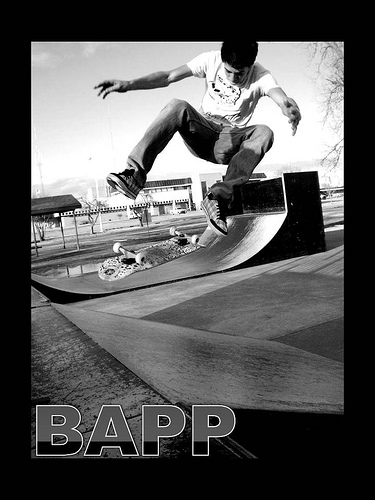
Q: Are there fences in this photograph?
A: No, there are no fences.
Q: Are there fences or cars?
A: No, there are no fences or cars.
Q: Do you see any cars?
A: No, there are no cars.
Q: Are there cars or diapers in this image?
A: No, there are no cars or diapers.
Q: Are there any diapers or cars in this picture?
A: No, there are no cars or diapers.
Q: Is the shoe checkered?
A: Yes, the shoe is checkered.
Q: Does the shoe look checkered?
A: Yes, the shoe is checkered.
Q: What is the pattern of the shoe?
A: The shoe is checkered.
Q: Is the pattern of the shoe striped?
A: No, the shoe is checkered.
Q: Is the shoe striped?
A: No, the shoe is checkered.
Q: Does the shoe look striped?
A: No, the shoe is checkered.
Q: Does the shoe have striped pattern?
A: No, the shoe is checkered.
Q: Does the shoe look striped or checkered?
A: The shoe is checkered.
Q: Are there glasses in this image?
A: No, there are no glasses.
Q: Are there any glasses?
A: No, there are no glasses.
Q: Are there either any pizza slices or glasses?
A: No, there are no glasses or pizza slices.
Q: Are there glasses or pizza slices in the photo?
A: No, there are no glasses or pizza slices.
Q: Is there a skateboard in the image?
A: Yes, there is a skateboard.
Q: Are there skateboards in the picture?
A: Yes, there is a skateboard.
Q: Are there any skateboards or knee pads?
A: Yes, there is a skateboard.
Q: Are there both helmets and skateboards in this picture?
A: No, there is a skateboard but no helmets.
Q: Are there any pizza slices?
A: No, there are no pizza slices.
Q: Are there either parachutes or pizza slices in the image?
A: No, there are no pizza slices or parachutes.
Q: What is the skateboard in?
A: The skateboard is in the air.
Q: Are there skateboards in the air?
A: Yes, there is a skateboard in the air.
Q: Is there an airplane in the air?
A: No, there is a skateboard in the air.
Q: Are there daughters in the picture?
A: No, there are no daughters.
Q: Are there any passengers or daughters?
A: No, there are no daughters or passengers.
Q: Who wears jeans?
A: The guy wears jeans.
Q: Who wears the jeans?
A: The guy wears jeans.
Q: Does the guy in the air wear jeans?
A: Yes, the guy wears jeans.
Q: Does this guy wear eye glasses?
A: No, the guy wears jeans.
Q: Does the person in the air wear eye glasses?
A: No, the guy wears jeans.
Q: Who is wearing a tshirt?
A: The guy is wearing a tshirt.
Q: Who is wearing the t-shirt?
A: The guy is wearing a tshirt.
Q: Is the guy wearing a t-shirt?
A: Yes, the guy is wearing a t-shirt.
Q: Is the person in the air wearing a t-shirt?
A: Yes, the guy is wearing a t-shirt.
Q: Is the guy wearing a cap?
A: No, the guy is wearing a t-shirt.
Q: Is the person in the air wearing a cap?
A: No, the guy is wearing a t-shirt.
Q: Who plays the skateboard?
A: The guy plays the skateboard.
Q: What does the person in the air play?
A: The guy plays the skateboard.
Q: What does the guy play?
A: The guy plays the skateboard.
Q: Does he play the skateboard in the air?
A: Yes, the guy plays the skateboard.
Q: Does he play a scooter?
A: No, the guy plays the skateboard.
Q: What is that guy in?
A: The guy is in the air.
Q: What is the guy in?
A: The guy is in the air.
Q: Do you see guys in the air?
A: Yes, there is a guy in the air.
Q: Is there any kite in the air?
A: No, there is a guy in the air.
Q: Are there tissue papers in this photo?
A: No, there are no tissue papers.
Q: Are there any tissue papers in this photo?
A: No, there are no tissue papers.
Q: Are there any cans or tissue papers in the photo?
A: No, there are no tissue papers or cans.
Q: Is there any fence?
A: No, there are no fences.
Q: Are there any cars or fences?
A: No, there are no fences or cars.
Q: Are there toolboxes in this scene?
A: No, there are no toolboxes.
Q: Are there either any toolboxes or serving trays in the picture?
A: No, there are no toolboxes or serving trays.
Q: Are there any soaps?
A: No, there are no soaps.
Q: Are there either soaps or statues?
A: No, there are no soaps or statues.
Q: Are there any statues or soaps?
A: No, there are no soaps or statues.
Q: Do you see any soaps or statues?
A: No, there are no soaps or statues.